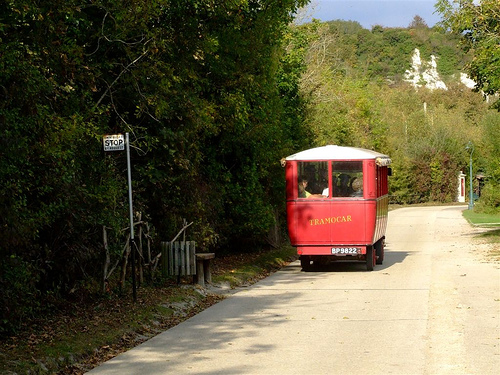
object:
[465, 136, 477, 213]
pole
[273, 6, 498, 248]
distance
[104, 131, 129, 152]
sign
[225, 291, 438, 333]
line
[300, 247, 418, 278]
shadow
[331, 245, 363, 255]
license plate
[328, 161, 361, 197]
window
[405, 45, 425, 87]
structure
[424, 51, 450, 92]
structure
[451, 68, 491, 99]
structure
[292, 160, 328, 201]
window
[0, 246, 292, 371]
grass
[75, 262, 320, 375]
shadows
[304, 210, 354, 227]
gold letters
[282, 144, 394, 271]
bus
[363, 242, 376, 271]
wheel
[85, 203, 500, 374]
floor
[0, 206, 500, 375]
ground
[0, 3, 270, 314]
tree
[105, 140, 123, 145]
stop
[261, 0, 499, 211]
background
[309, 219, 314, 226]
letter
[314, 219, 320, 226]
letter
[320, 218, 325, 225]
letter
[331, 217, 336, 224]
letter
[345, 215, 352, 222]
letter